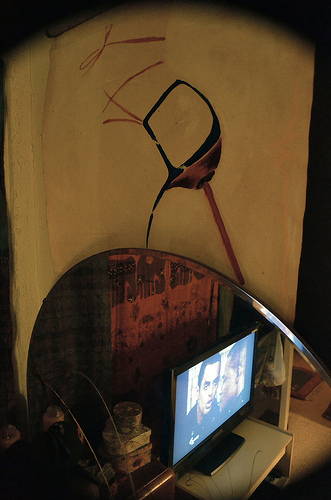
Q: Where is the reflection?
A: In mirror.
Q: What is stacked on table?
A: Boxes.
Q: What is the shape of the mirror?
A: Round.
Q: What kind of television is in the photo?
A: Flat screen.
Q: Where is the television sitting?
A: On table.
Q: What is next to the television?
A: End table.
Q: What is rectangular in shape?
A: Television.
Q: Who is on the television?
A: Actors.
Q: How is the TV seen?
A: Reflected in the mirror.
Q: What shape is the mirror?
A: Round.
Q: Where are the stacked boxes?
A: Next to the TV.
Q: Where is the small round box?
A: On top of the heart-shaped box.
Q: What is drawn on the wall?
A: A wine glass.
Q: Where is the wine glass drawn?
A: Above the mirror.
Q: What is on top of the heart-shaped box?
A: A small round box.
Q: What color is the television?
A: Black.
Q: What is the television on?
A: A table.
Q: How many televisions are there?
A: One.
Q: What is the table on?
A: The floor.